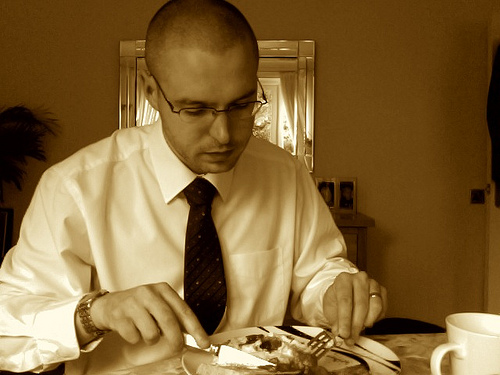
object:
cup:
[430, 311, 500, 374]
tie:
[182, 175, 227, 335]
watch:
[77, 289, 108, 339]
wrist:
[77, 289, 106, 337]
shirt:
[0, 117, 361, 375]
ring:
[368, 290, 383, 298]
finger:
[363, 280, 384, 328]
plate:
[180, 325, 401, 374]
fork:
[303, 329, 338, 360]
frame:
[119, 38, 316, 173]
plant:
[0, 105, 63, 203]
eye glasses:
[151, 73, 269, 123]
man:
[2, 0, 389, 373]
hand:
[321, 269, 389, 343]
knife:
[182, 332, 276, 371]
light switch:
[469, 188, 485, 205]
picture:
[313, 177, 335, 209]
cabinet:
[330, 209, 377, 272]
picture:
[336, 178, 358, 214]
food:
[195, 332, 369, 375]